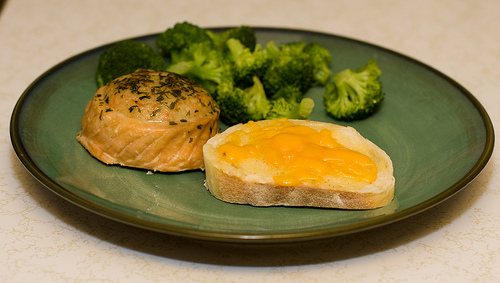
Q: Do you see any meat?
A: Yes, there is meat.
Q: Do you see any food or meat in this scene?
A: Yes, there is meat.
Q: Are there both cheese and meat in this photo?
A: Yes, there are both meat and cheese.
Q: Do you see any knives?
A: No, there are no knives.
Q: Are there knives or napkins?
A: No, there are no knives or napkins.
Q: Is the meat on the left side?
A: Yes, the meat is on the left of the image.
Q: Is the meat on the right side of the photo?
A: No, the meat is on the left of the image.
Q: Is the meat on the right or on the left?
A: The meat is on the left of the image.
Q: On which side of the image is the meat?
A: The meat is on the left of the image.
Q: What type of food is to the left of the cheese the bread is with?
A: The food is meat.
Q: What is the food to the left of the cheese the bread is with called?
A: The food is meat.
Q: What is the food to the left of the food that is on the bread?
A: The food is meat.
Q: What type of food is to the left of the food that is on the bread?
A: The food is meat.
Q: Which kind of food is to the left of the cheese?
A: The food is meat.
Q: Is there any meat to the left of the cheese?
A: Yes, there is meat to the left of the cheese.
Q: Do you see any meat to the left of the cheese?
A: Yes, there is meat to the left of the cheese.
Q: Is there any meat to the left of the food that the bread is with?
A: Yes, there is meat to the left of the cheese.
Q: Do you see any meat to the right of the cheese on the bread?
A: No, the meat is to the left of the cheese.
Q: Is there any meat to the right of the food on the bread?
A: No, the meat is to the left of the cheese.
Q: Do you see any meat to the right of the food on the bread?
A: No, the meat is to the left of the cheese.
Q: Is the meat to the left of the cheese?
A: Yes, the meat is to the left of the cheese.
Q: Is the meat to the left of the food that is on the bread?
A: Yes, the meat is to the left of the cheese.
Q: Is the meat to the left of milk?
A: No, the meat is to the left of the cheese.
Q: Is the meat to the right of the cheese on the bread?
A: No, the meat is to the left of the cheese.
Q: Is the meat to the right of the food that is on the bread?
A: No, the meat is to the left of the cheese.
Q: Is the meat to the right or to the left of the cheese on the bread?
A: The meat is to the left of the cheese.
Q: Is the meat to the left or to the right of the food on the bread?
A: The meat is to the left of the cheese.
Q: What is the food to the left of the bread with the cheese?
A: The food is meat.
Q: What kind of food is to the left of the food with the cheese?
A: The food is meat.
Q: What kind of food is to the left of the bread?
A: The food is meat.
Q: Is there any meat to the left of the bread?
A: Yes, there is meat to the left of the bread.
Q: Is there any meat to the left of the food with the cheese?
A: Yes, there is meat to the left of the bread.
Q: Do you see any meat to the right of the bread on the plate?
A: No, the meat is to the left of the bread.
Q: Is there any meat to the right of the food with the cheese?
A: No, the meat is to the left of the bread.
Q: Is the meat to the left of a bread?
A: Yes, the meat is to the left of a bread.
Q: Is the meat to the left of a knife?
A: No, the meat is to the left of a bread.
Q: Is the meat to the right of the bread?
A: No, the meat is to the left of the bread.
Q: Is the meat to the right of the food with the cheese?
A: No, the meat is to the left of the bread.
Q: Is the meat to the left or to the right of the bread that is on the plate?
A: The meat is to the left of the bread.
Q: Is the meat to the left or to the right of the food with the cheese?
A: The meat is to the left of the bread.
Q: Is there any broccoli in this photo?
A: Yes, there is broccoli.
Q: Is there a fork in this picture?
A: No, there are no forks.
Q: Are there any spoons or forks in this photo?
A: No, there are no forks or spoons.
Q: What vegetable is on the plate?
A: The vegetable is broccoli.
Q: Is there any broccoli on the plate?
A: Yes, there is broccoli on the plate.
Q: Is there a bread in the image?
A: Yes, there is a bread.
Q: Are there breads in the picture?
A: Yes, there is a bread.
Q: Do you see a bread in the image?
A: Yes, there is a bread.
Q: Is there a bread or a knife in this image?
A: Yes, there is a bread.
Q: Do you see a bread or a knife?
A: Yes, there is a bread.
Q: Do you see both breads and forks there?
A: No, there is a bread but no forks.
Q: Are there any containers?
A: No, there are no containers.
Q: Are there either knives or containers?
A: No, there are no containers or knives.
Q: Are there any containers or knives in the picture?
A: No, there are no containers or knives.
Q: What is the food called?
A: The food is a bread.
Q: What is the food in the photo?
A: The food is a bread.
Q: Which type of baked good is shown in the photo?
A: The baked good is a bread.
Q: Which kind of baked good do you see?
A: The baked good is a bread.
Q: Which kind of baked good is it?
A: The food is a bread.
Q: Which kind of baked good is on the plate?
A: The food is a bread.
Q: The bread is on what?
A: The bread is on the plate.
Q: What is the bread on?
A: The bread is on the plate.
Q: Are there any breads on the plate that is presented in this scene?
A: Yes, there is a bread on the plate.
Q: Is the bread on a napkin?
A: No, the bread is on the plate.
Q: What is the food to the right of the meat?
A: The food is a bread.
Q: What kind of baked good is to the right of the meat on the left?
A: The food is a bread.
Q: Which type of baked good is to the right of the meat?
A: The food is a bread.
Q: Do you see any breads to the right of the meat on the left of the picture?
A: Yes, there is a bread to the right of the meat.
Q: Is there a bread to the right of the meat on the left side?
A: Yes, there is a bread to the right of the meat.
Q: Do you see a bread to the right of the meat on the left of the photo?
A: Yes, there is a bread to the right of the meat.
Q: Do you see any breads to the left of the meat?
A: No, the bread is to the right of the meat.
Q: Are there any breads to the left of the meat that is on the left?
A: No, the bread is to the right of the meat.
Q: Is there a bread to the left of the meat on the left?
A: No, the bread is to the right of the meat.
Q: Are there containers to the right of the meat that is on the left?
A: No, there is a bread to the right of the meat.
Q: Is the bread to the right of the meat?
A: Yes, the bread is to the right of the meat.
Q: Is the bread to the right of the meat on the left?
A: Yes, the bread is to the right of the meat.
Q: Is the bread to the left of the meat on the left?
A: No, the bread is to the right of the meat.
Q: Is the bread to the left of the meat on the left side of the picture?
A: No, the bread is to the right of the meat.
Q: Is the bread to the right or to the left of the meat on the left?
A: The bread is to the right of the meat.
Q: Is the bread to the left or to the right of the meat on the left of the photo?
A: The bread is to the right of the meat.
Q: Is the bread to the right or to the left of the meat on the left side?
A: The bread is to the right of the meat.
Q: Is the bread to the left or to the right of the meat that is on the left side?
A: The bread is to the right of the meat.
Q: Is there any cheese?
A: Yes, there is cheese.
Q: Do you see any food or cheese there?
A: Yes, there is cheese.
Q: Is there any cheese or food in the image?
A: Yes, there is cheese.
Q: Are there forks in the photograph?
A: No, there are no forks.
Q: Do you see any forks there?
A: No, there are no forks.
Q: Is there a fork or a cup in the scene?
A: No, there are no forks or cups.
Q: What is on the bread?
A: The cheese is on the bread.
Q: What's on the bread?
A: The cheese is on the bread.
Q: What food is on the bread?
A: The food is cheese.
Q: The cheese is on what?
A: The cheese is on the bread.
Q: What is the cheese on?
A: The cheese is on the bread.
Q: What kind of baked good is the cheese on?
A: The cheese is on the bread.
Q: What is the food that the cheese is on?
A: The food is a bread.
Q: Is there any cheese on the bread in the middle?
A: Yes, there is cheese on the bread.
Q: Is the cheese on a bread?
A: Yes, the cheese is on a bread.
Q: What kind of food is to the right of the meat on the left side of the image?
A: The food is cheese.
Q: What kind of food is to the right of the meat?
A: The food is cheese.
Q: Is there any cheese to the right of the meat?
A: Yes, there is cheese to the right of the meat.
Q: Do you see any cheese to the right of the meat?
A: Yes, there is cheese to the right of the meat.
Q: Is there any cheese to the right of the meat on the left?
A: Yes, there is cheese to the right of the meat.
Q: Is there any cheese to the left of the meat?
A: No, the cheese is to the right of the meat.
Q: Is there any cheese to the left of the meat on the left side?
A: No, the cheese is to the right of the meat.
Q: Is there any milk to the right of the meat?
A: No, there is cheese to the right of the meat.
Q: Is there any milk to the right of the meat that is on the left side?
A: No, there is cheese to the right of the meat.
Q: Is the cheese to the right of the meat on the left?
A: Yes, the cheese is to the right of the meat.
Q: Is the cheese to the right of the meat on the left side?
A: Yes, the cheese is to the right of the meat.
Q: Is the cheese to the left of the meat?
A: No, the cheese is to the right of the meat.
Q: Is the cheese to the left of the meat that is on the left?
A: No, the cheese is to the right of the meat.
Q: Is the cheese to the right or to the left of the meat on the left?
A: The cheese is to the right of the meat.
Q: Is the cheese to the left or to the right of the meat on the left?
A: The cheese is to the right of the meat.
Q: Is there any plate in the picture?
A: Yes, there is a plate.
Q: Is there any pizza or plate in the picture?
A: Yes, there is a plate.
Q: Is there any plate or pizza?
A: Yes, there is a plate.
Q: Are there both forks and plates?
A: No, there is a plate but no forks.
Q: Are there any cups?
A: No, there are no cups.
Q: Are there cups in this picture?
A: No, there are no cups.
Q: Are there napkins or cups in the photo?
A: No, there are no cups or napkins.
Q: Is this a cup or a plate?
A: This is a plate.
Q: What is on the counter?
A: The plate is on the counter.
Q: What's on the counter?
A: The plate is on the counter.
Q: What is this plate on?
A: The plate is on the counter.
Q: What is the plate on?
A: The plate is on the counter.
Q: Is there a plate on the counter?
A: Yes, there is a plate on the counter.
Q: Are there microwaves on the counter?
A: No, there is a plate on the counter.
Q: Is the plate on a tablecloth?
A: No, the plate is on a counter.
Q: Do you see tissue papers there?
A: No, there are no tissue papers.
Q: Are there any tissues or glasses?
A: No, there are no tissues or glasses.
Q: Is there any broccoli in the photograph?
A: Yes, there is broccoli.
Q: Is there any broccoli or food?
A: Yes, there is broccoli.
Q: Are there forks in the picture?
A: No, there are no forks.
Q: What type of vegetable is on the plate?
A: The vegetable is broccoli.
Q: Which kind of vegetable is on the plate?
A: The vegetable is broccoli.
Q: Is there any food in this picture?
A: Yes, there is food.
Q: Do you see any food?
A: Yes, there is food.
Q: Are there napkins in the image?
A: No, there are no napkins.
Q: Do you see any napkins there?
A: No, there are no napkins.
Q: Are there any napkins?
A: No, there are no napkins.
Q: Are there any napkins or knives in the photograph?
A: No, there are no napkins or knives.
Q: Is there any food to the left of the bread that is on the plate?
A: Yes, there is food to the left of the bread.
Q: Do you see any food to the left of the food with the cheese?
A: Yes, there is food to the left of the bread.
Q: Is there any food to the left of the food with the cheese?
A: Yes, there is food to the left of the bread.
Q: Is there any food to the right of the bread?
A: No, the food is to the left of the bread.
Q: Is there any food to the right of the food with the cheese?
A: No, the food is to the left of the bread.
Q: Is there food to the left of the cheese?
A: Yes, there is food to the left of the cheese.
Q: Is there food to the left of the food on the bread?
A: Yes, there is food to the left of the cheese.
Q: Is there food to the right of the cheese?
A: No, the food is to the left of the cheese.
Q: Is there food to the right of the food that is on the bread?
A: No, the food is to the left of the cheese.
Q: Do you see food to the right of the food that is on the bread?
A: No, the food is to the left of the cheese.